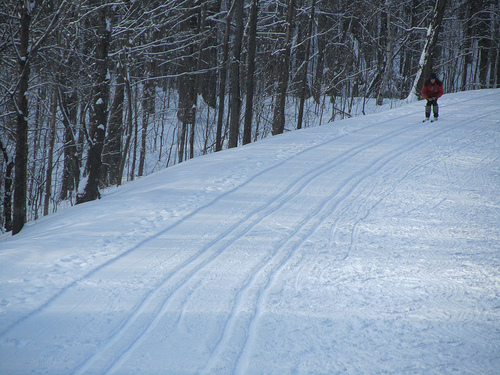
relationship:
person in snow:
[422, 73, 443, 123] [2, 86, 499, 375]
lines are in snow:
[82, 98, 496, 375] [2, 86, 499, 375]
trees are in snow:
[2, 0, 498, 239] [2, 86, 499, 375]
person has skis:
[422, 73, 443, 123] [423, 116, 439, 123]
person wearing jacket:
[422, 73, 443, 123] [423, 80, 445, 98]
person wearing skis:
[422, 73, 443, 123] [423, 116, 439, 123]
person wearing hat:
[422, 73, 443, 123] [429, 72, 437, 80]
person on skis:
[422, 73, 443, 123] [423, 116, 439, 123]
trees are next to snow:
[2, 0, 498, 239] [2, 86, 499, 375]